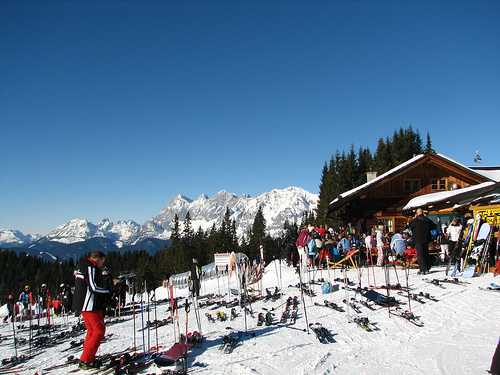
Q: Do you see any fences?
A: No, there are no fences.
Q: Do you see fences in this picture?
A: No, there are no fences.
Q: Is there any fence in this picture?
A: No, there are no fences.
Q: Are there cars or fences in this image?
A: No, there are no fences or cars.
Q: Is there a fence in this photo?
A: No, there are no fences.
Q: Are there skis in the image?
A: Yes, there are skis.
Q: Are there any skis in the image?
A: Yes, there are skis.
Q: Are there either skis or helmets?
A: Yes, there are skis.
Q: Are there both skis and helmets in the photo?
A: Yes, there are both skis and a helmet.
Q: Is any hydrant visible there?
A: No, there are no fire hydrants.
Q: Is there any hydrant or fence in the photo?
A: No, there are no fire hydrants or fences.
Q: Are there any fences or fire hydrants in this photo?
A: No, there are no fire hydrants or fences.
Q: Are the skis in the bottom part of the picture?
A: Yes, the skis are in the bottom of the image.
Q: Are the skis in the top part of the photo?
A: No, the skis are in the bottom of the image.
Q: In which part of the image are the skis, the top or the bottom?
A: The skis are in the bottom of the image.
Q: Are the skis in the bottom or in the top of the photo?
A: The skis are in the bottom of the image.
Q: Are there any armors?
A: No, there are no armors.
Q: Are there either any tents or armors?
A: No, there are no armors or tents.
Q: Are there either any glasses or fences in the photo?
A: No, there are no fences or glasses.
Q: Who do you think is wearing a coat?
A: The man is wearing a coat.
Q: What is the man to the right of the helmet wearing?
A: The man is wearing a coat.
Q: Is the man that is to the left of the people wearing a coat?
A: Yes, the man is wearing a coat.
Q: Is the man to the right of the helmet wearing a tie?
A: No, the man is wearing a coat.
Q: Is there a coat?
A: Yes, there is a coat.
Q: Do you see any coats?
A: Yes, there is a coat.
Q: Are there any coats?
A: Yes, there is a coat.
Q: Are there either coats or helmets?
A: Yes, there is a coat.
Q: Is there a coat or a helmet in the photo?
A: Yes, there is a coat.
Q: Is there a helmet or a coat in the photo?
A: Yes, there is a coat.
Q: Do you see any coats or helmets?
A: Yes, there is a coat.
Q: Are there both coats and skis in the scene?
A: Yes, there are both a coat and skis.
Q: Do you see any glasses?
A: No, there are no glasses.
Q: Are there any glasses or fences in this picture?
A: No, there are no glasses or fences.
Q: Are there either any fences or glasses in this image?
A: No, there are no glasses or fences.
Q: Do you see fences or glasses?
A: No, there are no glasses or fences.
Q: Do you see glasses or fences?
A: No, there are no glasses or fences.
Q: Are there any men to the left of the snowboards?
A: Yes, there is a man to the left of the snowboards.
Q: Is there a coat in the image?
A: Yes, there is a coat.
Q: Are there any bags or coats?
A: Yes, there is a coat.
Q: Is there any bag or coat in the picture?
A: Yes, there is a coat.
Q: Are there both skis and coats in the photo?
A: Yes, there are both a coat and skis.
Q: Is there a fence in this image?
A: No, there are no fences.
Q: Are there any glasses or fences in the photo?
A: No, there are no fences or glasses.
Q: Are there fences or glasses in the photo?
A: No, there are no fences or glasses.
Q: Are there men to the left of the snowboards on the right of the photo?
A: Yes, there is a man to the left of the snowboards.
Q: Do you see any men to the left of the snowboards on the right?
A: Yes, there is a man to the left of the snowboards.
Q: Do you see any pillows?
A: No, there are no pillows.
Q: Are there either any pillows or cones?
A: No, there are no pillows or cones.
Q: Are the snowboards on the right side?
A: Yes, the snowboards are on the right of the image.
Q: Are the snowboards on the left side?
A: No, the snowboards are on the right of the image.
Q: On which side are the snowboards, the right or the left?
A: The snowboards are on the right of the image.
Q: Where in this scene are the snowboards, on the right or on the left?
A: The snowboards are on the right of the image.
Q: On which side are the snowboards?
A: The snowboards are on the right of the image.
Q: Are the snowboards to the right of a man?
A: Yes, the snowboards are to the right of a man.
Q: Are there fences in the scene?
A: No, there are no fences.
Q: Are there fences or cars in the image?
A: No, there are no fences or cars.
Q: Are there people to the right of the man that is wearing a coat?
A: Yes, there are people to the right of the man.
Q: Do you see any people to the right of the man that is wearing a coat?
A: Yes, there are people to the right of the man.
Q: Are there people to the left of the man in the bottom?
A: No, the people are to the right of the man.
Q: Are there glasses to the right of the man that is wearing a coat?
A: No, there are people to the right of the man.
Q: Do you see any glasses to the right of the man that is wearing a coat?
A: No, there are people to the right of the man.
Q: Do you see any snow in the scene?
A: Yes, there is snow.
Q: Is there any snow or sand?
A: Yes, there is snow.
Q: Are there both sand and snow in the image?
A: No, there is snow but no sand.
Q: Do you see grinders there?
A: No, there are no grinders.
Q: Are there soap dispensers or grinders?
A: No, there are no grinders or soap dispensers.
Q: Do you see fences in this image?
A: No, there are no fences.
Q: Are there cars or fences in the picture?
A: No, there are no fences or cars.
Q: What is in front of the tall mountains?
A: The trees are in front of the mountains.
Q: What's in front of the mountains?
A: The trees are in front of the mountains.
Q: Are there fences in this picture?
A: No, there are no fences.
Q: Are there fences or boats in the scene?
A: No, there are no fences or boats.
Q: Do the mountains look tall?
A: Yes, the mountains are tall.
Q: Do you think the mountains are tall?
A: Yes, the mountains are tall.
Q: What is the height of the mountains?
A: The mountains are tall.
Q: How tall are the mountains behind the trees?
A: The mountains are tall.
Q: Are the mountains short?
A: No, the mountains are tall.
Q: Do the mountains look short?
A: No, the mountains are tall.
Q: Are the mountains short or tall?
A: The mountains are tall.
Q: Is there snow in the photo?
A: Yes, there is snow.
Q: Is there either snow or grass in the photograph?
A: Yes, there is snow.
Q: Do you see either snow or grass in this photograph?
A: Yes, there is snow.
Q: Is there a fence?
A: No, there are no fences.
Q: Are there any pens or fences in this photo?
A: No, there are no fences or pens.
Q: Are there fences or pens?
A: No, there are no fences or pens.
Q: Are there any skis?
A: Yes, there are skis.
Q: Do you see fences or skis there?
A: Yes, there are skis.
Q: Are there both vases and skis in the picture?
A: No, there are skis but no vases.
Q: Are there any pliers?
A: No, there are no pliers.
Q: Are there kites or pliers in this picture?
A: No, there are no pliers or kites.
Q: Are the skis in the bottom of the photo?
A: Yes, the skis are in the bottom of the image.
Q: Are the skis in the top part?
A: No, the skis are in the bottom of the image.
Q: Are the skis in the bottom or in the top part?
A: The skis are in the bottom of the image.